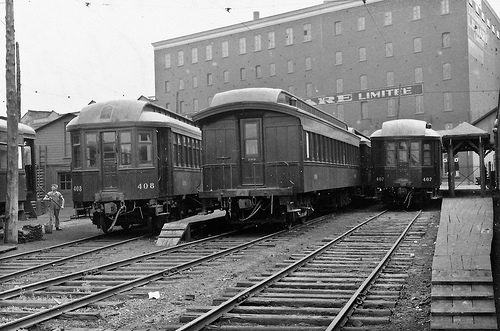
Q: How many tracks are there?
A: Three.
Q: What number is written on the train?
A: 408.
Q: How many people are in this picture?
A: One.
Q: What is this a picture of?
A: Train station.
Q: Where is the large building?
A: In the back.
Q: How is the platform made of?
A: Wood.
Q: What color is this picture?
A: Black and white.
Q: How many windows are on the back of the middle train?
A: One.